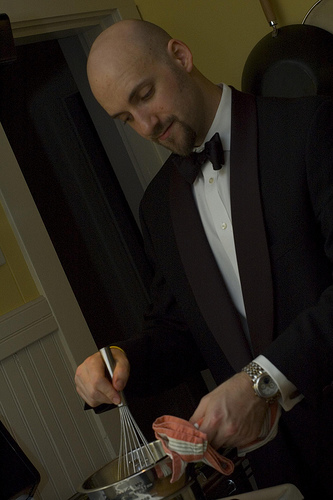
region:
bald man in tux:
[54, 24, 305, 288]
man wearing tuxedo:
[73, 24, 274, 267]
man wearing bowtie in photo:
[67, 24, 287, 237]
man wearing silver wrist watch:
[202, 330, 310, 468]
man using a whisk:
[42, 312, 207, 495]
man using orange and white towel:
[139, 371, 305, 492]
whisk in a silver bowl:
[50, 328, 176, 499]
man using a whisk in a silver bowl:
[81, 37, 275, 494]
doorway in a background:
[9, 39, 288, 485]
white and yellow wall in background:
[4, 210, 152, 497]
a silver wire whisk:
[75, 333, 188, 486]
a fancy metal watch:
[231, 353, 296, 411]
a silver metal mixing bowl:
[56, 426, 233, 497]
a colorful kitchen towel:
[134, 394, 252, 486]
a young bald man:
[63, 11, 267, 160]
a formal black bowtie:
[171, 129, 234, 187]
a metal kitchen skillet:
[235, 0, 331, 117]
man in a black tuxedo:
[67, 17, 330, 459]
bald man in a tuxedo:
[52, 9, 331, 416]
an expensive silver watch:
[218, 343, 298, 412]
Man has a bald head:
[82, 13, 185, 79]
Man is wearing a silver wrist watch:
[240, 360, 281, 408]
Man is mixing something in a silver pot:
[71, 343, 209, 498]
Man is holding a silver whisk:
[95, 347, 157, 496]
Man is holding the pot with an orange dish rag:
[152, 412, 286, 483]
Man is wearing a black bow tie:
[165, 131, 234, 184]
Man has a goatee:
[148, 113, 199, 159]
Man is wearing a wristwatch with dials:
[237, 357, 289, 409]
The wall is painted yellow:
[0, 210, 48, 356]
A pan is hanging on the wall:
[218, 0, 332, 107]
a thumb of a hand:
[111, 357, 127, 389]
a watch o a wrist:
[247, 365, 278, 404]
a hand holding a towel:
[176, 416, 214, 451]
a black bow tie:
[169, 143, 230, 181]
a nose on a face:
[133, 112, 161, 142]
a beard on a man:
[166, 137, 193, 159]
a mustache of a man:
[153, 119, 177, 140]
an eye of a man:
[131, 87, 163, 105]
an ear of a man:
[166, 37, 199, 76]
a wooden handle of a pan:
[258, 5, 285, 45]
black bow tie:
[168, 133, 230, 182]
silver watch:
[242, 362, 281, 400]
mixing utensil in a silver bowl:
[111, 379, 153, 478]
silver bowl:
[82, 443, 186, 497]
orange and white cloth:
[153, 415, 231, 484]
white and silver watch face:
[254, 371, 276, 397]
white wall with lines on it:
[2, 309, 78, 431]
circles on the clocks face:
[258, 375, 275, 392]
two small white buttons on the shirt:
[203, 172, 226, 235]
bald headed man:
[85, 16, 220, 159]